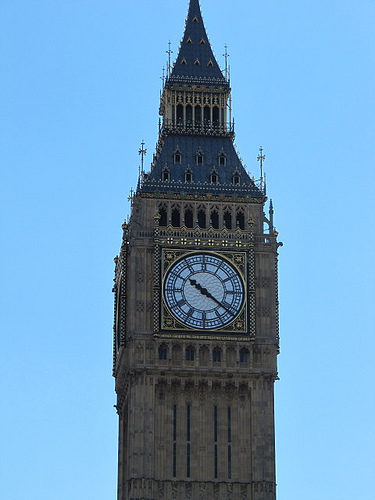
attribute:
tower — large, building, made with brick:
[122, 2, 280, 500]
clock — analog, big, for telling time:
[163, 252, 247, 333]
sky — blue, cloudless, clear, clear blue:
[6, 6, 122, 133]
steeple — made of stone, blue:
[155, 1, 243, 140]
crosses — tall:
[136, 144, 272, 194]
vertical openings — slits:
[168, 399, 238, 483]